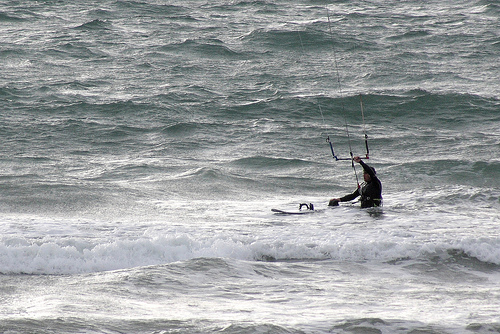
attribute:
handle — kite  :
[295, 195, 343, 211]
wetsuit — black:
[346, 164, 391, 213]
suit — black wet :
[318, 172, 389, 214]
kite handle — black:
[314, 125, 379, 161]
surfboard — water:
[243, 203, 343, 231]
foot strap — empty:
[298, 198, 313, 210]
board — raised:
[263, 202, 343, 213]